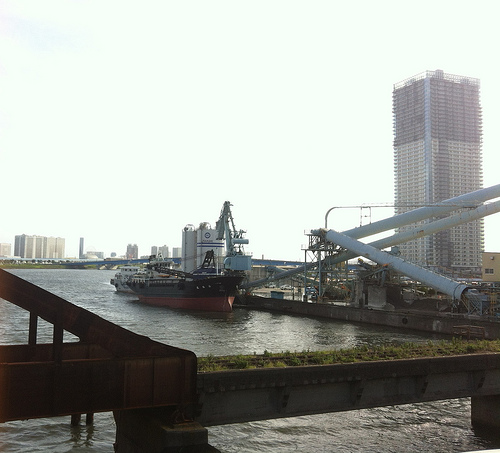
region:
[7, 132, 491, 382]
the scene is at the sea port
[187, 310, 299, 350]
the water are colorles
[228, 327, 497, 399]
the pass way is old and rugged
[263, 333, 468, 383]
the pass way has green plants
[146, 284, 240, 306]
the boat is red in color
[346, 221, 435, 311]
the pipes are mettalic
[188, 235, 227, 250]
the walls has blue stripes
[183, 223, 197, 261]
the building walls are blue in color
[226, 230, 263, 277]
the plates are white in color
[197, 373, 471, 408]
the highway is dirty and rugged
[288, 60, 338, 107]
part of a cloud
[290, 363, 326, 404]
edge of a bridge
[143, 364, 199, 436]
part of a metal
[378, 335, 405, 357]
part of a grass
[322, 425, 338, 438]
part of a water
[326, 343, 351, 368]
part of a grass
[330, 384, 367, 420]
edge of a bridge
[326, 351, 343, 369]
edge of a bridge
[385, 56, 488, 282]
building with several stories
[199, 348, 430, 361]
grass area on bridge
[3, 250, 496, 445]
bridge area near water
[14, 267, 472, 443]
body of water with boat in it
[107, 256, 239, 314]
boats in the water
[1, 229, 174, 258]
buildings on land across water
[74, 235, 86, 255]
building standing alone from other buildings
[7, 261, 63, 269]
grassy land across from water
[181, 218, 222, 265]
round buildings near view of boat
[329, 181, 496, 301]
white tubes near boat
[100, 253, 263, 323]
Ship is stationary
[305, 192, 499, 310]
White pole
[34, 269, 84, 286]
Waves are still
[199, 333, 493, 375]
Grass on the metal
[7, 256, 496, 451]
Bridge has rusted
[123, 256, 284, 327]
Boat is black and red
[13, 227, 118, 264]
Buildings in the background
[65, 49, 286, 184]
It is sunny in the shot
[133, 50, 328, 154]
There are no clouds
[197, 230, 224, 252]
Logo is on the building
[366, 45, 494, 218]
LARGE BUILDING UNDER CONSTRUCTION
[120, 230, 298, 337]
LARGE SHIP IN RIVER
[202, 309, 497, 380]
PLANTS GROWING ON OLD BRIDGE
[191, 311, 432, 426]
OLD BRIDGE CROSSING OVER RIVER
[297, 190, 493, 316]
WHITE POLES ON SIDE OF RIVER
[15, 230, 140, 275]
HIGH RISES IN BACKGROUND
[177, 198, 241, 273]
CONCRETE PLANT BY SHIP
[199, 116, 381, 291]
OVERCAST SKY ABOVE RIVER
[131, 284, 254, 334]
RED BOTTOM OF LARGE SHIP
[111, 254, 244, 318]
BLACK SIDE OF LARGE SHIP